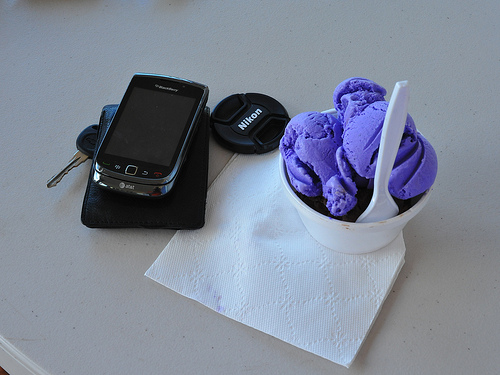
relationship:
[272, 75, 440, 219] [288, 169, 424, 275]
ice cream in bowl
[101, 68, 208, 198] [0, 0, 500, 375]
cellphone on a surfboard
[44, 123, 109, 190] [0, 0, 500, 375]
black key on a surfboard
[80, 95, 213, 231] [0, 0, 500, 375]
wallet on a surfboard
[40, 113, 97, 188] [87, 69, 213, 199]
black key nex tto cellphone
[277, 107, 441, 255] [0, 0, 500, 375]
bowl on surfboard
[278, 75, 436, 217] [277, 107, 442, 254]
ice cream in bowl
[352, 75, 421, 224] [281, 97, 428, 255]
spoon in bowl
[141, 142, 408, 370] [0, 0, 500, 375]
bad napkin on surfboard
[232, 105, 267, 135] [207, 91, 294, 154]
brand name on camera lens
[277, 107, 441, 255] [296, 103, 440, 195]
bowl of ice cream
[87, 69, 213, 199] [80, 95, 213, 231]
cellphone on wallet